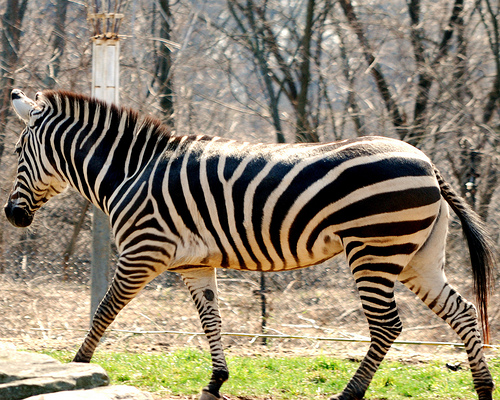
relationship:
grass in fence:
[27, 349, 497, 398] [6, 176, 490, 291]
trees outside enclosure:
[336, 3, 480, 138] [12, 51, 495, 361]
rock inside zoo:
[0, 348, 105, 398] [9, 47, 499, 387]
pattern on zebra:
[139, 160, 411, 251] [4, 85, 497, 400]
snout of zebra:
[0, 202, 33, 227] [4, 85, 498, 396]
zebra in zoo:
[4, 85, 498, 396] [9, 47, 499, 387]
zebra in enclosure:
[4, 85, 498, 396] [12, 51, 495, 361]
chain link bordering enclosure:
[22, 223, 99, 317] [12, 51, 495, 361]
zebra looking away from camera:
[4, 85, 497, 400] [375, 50, 483, 382]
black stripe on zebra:
[349, 262, 408, 273] [4, 85, 498, 396]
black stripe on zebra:
[332, 212, 440, 238] [4, 85, 498, 396]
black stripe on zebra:
[119, 261, 161, 271] [4, 85, 498, 396]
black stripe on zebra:
[369, 348, 384, 364] [4, 85, 498, 396]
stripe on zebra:
[113, 102, 129, 212] [25, 97, 493, 374]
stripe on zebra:
[356, 286, 393, 298] [4, 85, 498, 396]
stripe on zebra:
[259, 151, 288, 264] [12, 76, 497, 377]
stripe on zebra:
[327, 192, 383, 252] [4, 85, 498, 396]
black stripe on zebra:
[345, 262, 407, 273] [4, 85, 498, 396]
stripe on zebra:
[105, 98, 126, 232] [4, 85, 498, 396]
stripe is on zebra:
[6, 102, 490, 385] [4, 85, 498, 396]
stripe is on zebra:
[351, 241, 419, 258] [4, 85, 498, 396]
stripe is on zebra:
[404, 282, 419, 291] [4, 85, 498, 396]